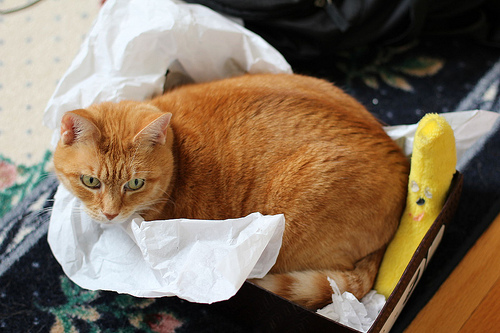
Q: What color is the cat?
A: Orange.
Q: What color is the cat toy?
A: Yellow.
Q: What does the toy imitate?
A: A banana.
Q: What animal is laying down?
A: Cat.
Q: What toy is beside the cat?
A: Plush banana.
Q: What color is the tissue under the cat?
A: White.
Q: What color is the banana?
A: Yellow.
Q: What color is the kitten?
A: Orange.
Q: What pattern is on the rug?
A: Flowers.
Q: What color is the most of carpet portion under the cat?
A: Blue.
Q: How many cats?
A: One.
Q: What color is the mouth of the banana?
A: Pink.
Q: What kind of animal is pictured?
A: Cat.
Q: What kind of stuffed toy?
A: Banana.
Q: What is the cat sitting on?
A: Tissue paper.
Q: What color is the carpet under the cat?
A: Blue.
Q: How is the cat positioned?
A: Laying.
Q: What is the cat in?
A: A box.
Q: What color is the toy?
A: Yellow.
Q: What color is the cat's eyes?
A: Green.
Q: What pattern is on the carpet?
A: Flowers.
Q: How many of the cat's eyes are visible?
A: 2.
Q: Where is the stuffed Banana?
A: Behind the cat.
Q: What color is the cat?
A: Orange.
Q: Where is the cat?
A: In a box.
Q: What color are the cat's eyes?
A: Green.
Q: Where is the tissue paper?
A: Under the cat.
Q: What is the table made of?
A: Wood.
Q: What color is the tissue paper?
A: White.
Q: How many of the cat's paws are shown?
A: None.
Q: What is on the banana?
A: Face.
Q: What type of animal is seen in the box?
A: Cat.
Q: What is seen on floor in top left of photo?
A: Linoleum.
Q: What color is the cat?
A: Orange.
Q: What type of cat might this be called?
A: Tabby.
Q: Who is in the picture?
A: A cat.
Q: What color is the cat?
A: Orange.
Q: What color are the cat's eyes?
A: Green.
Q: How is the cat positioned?
A: Curled up.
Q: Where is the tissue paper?
A: Underneath the cat.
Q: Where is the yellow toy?
A: To the right of the cat.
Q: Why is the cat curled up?
A: It's resting.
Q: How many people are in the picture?
A: None.